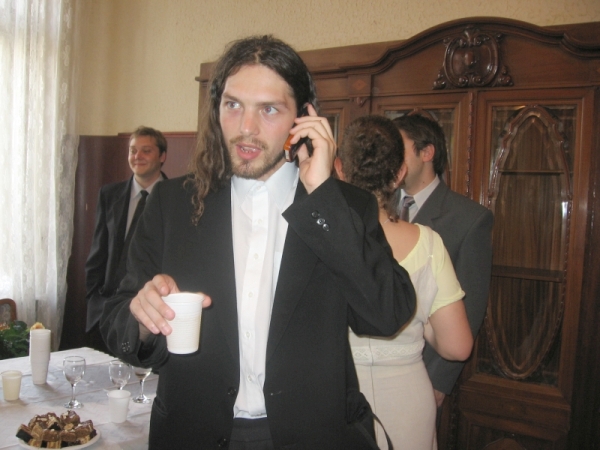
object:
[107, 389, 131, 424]
drink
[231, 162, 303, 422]
shirt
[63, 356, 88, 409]
glass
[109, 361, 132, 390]
glass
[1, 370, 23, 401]
cup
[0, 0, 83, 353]
curtain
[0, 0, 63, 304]
window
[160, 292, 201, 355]
cup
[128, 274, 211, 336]
hand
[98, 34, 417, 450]
man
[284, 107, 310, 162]
phone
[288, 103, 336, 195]
hand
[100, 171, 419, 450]
blazer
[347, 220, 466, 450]
dress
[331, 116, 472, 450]
woman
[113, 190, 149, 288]
tie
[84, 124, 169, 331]
man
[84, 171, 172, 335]
suit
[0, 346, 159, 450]
table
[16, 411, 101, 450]
plate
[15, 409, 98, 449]
pastries